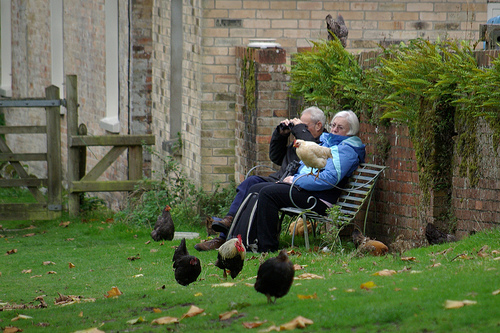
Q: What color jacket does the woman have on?
A: Blue.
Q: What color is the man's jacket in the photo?
A: Black.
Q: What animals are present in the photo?
A: Chickens.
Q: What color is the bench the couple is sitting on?
A: Green.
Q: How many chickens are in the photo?
A: Seven.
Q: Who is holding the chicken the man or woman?
A: Woman.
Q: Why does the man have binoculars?
A: To see.